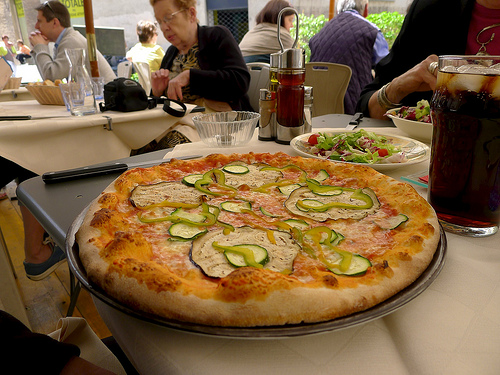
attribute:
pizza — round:
[74, 155, 442, 327]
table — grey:
[19, 152, 497, 369]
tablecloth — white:
[96, 142, 500, 372]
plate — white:
[289, 127, 431, 166]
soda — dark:
[430, 55, 498, 235]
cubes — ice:
[436, 62, 499, 98]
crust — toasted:
[81, 156, 437, 325]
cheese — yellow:
[102, 153, 433, 291]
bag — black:
[105, 79, 187, 115]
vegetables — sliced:
[167, 164, 407, 278]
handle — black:
[44, 165, 128, 188]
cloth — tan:
[0, 101, 194, 176]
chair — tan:
[299, 57, 357, 117]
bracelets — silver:
[373, 84, 394, 112]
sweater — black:
[157, 22, 249, 111]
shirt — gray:
[34, 25, 116, 96]